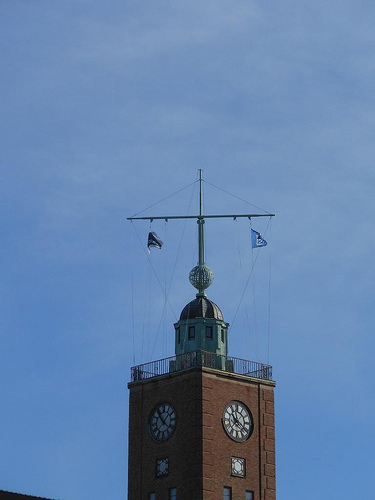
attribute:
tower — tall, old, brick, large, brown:
[113, 163, 288, 500]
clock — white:
[218, 393, 259, 444]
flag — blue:
[242, 222, 280, 256]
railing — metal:
[126, 349, 275, 394]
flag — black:
[141, 226, 174, 254]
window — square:
[218, 482, 239, 499]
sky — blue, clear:
[75, 63, 308, 373]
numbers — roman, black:
[224, 402, 252, 440]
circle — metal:
[171, 255, 226, 295]